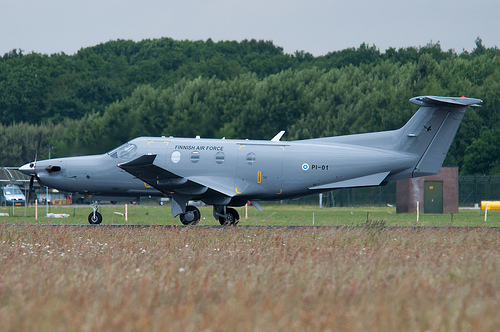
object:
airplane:
[6, 94, 484, 228]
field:
[0, 205, 500, 332]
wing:
[117, 152, 234, 218]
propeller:
[7, 131, 46, 204]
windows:
[170, 150, 181, 164]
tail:
[401, 93, 483, 180]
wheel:
[178, 204, 201, 226]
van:
[0, 186, 29, 207]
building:
[394, 167, 459, 216]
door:
[235, 144, 285, 195]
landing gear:
[88, 200, 103, 224]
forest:
[0, 35, 500, 207]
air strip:
[280, 211, 323, 243]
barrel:
[478, 199, 500, 211]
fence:
[0, 199, 500, 223]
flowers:
[44, 245, 50, 250]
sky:
[0, 0, 500, 59]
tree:
[0, 73, 50, 113]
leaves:
[335, 73, 353, 85]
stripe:
[236, 142, 289, 146]